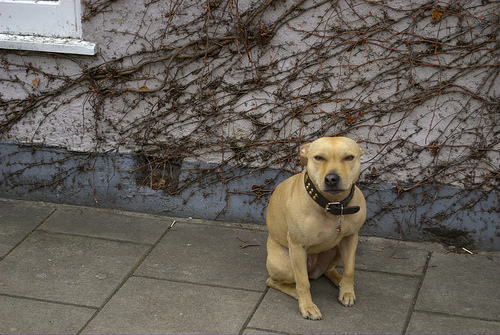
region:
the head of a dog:
[265, 118, 414, 195]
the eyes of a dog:
[296, 142, 379, 177]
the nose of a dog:
[306, 156, 366, 212]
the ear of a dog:
[288, 109, 337, 165]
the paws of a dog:
[279, 255, 409, 320]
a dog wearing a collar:
[283, 131, 381, 231]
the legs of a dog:
[271, 228, 395, 318]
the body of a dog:
[222, 130, 418, 311]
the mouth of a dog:
[296, 163, 379, 208]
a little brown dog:
[248, 140, 388, 314]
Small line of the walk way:
[35, 223, 157, 255]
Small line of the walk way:
[356, 260, 420, 281]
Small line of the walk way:
[131, 266, 263, 302]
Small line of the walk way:
[245, 320, 284, 334]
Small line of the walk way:
[413, 309, 468, 334]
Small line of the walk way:
[411, 238, 443, 333]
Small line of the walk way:
[222, 279, 290, 331]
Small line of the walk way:
[135, 216, 182, 273]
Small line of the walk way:
[65, 258, 113, 328]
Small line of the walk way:
[4, 281, 114, 332]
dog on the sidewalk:
[243, 136, 375, 303]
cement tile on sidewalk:
[66, 213, 158, 237]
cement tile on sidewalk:
[20, 238, 114, 298]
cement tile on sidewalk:
[176, 228, 266, 293]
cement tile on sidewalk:
[118, 285, 230, 330]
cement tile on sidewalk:
[291, 284, 383, 326]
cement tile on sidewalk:
[350, 236, 418, 266]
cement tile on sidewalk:
[428, 250, 495, 311]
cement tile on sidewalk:
[413, 311, 485, 331]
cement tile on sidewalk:
[4, 212, 34, 239]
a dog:
[250, 124, 382, 321]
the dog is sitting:
[255, 130, 395, 315]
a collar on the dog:
[330, 197, 353, 216]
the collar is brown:
[318, 196, 348, 215]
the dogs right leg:
[294, 275, 325, 320]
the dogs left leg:
[337, 260, 361, 305]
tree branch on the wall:
[136, 42, 186, 79]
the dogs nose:
[321, 172, 336, 186]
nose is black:
[320, 171, 342, 189]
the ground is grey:
[80, 245, 180, 302]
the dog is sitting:
[258, 125, 388, 322]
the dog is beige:
[250, 125, 387, 333]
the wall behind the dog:
[12, 0, 487, 265]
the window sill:
[1, 33, 94, 55]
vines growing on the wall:
[162, 10, 479, 162]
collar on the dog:
[299, 170, 377, 230]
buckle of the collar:
[325, 198, 347, 218]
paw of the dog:
[296, 295, 326, 325]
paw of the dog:
[332, 282, 360, 307]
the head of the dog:
[292, 133, 372, 199]